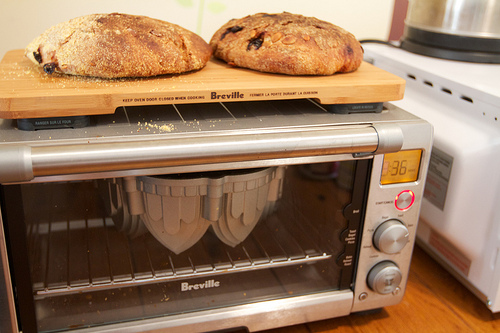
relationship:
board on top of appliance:
[0, 49, 405, 119] [0, 101, 433, 330]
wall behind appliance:
[12, 4, 411, 41] [0, 101, 433, 330]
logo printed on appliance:
[176, 277, 236, 315] [4, 99, 416, 331]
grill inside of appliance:
[26, 239, 329, 279] [7, 124, 421, 324]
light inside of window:
[378, 149, 428, 197] [378, 142, 418, 185]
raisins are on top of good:
[230, 12, 328, 43] [217, 10, 359, 88]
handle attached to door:
[20, 131, 390, 183] [10, 121, 371, 321]